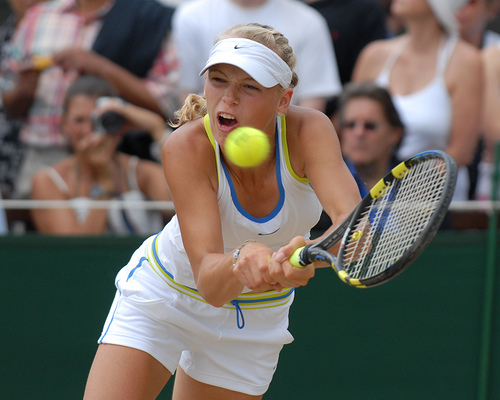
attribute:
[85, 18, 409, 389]
woman — wearing, taking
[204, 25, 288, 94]
visor — white, nike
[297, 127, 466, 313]
racket — tennis, part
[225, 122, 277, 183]
ball — tennis, part, yellow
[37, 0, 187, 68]
man — wearing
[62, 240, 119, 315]
wall — part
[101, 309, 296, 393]
short — part, tennis, white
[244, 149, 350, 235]
shirt — part, plaid, blue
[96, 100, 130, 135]
camera — part, black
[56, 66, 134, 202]
spectator — female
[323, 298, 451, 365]
fence — green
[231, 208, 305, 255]
tank — white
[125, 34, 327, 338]
she — holding, hitting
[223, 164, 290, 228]
neckline — blue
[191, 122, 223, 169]
line — sleeve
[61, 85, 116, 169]
person — taking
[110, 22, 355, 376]
player — tennis, female